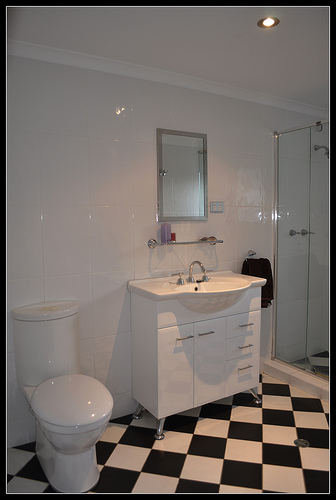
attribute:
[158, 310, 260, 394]
cabinet — white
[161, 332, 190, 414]
door — shut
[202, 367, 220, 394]
door — shut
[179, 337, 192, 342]
handle — silver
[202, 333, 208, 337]
handle — silver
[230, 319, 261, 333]
drawer — shut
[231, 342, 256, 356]
drawer — shut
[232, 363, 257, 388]
drawer — shut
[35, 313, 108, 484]
toliet — white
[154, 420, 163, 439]
leg — silver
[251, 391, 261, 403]
leg — silver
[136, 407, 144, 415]
leg — silver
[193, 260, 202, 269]
faucet — silver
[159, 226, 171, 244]
candle — purple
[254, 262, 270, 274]
towel — brown